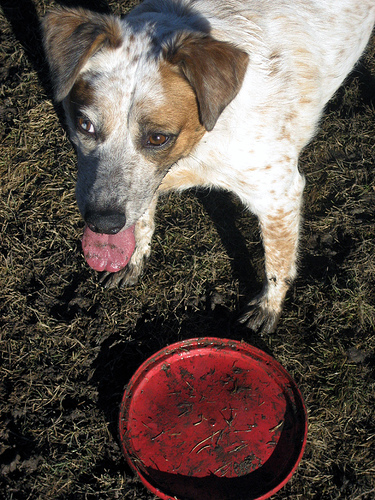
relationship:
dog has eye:
[50, 0, 368, 333] [145, 130, 168, 146]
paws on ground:
[111, 259, 285, 333] [9, 303, 142, 367]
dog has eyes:
[50, 10, 333, 302] [75, 110, 168, 146]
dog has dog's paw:
[50, 0, 368, 333] [235, 297, 283, 340]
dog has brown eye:
[50, 0, 368, 333] [146, 129, 173, 147]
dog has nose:
[50, 10, 333, 302] [81, 211, 125, 234]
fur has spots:
[116, 29, 167, 108] [125, 35, 140, 64]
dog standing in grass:
[50, 0, 368, 333] [41, 226, 363, 364]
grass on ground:
[0, 1, 374, 497] [17, 281, 361, 486]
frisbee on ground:
[116, 332, 311, 490] [2, 4, 370, 497]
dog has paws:
[50, 0, 368, 333] [104, 252, 277, 325]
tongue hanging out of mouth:
[76, 227, 140, 270] [71, 193, 156, 279]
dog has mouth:
[50, 0, 368, 333] [71, 193, 156, 279]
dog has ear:
[50, 0, 368, 333] [159, 22, 251, 132]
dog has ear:
[50, 0, 368, 333] [35, 4, 126, 102]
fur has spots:
[33, 0, 372, 288] [261, 207, 296, 278]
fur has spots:
[33, 0, 372, 288] [268, 49, 320, 141]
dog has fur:
[50, 10, 333, 302] [33, 0, 372, 288]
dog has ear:
[50, 0, 368, 333] [42, 10, 110, 101]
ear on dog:
[171, 34, 254, 135] [50, 0, 368, 333]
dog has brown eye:
[50, 0, 368, 333] [146, 134, 170, 147]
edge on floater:
[113, 374, 149, 485] [112, 330, 309, 496]